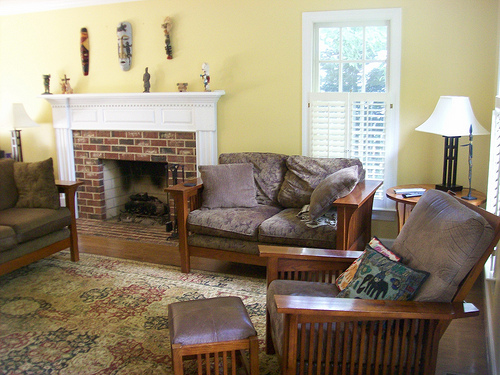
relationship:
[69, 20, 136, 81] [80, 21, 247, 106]
decorations on wall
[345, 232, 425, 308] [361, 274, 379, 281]
pillow has image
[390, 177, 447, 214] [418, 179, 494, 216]
controls on tabel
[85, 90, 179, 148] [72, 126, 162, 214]
mantle on fireplace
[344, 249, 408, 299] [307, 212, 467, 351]
pillows on chair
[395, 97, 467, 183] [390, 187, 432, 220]
lamp on table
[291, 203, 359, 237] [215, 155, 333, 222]
control on couch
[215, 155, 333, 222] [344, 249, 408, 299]
couch with pillows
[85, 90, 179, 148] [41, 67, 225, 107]
mantle has figures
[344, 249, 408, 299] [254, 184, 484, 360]
pillows are on chair